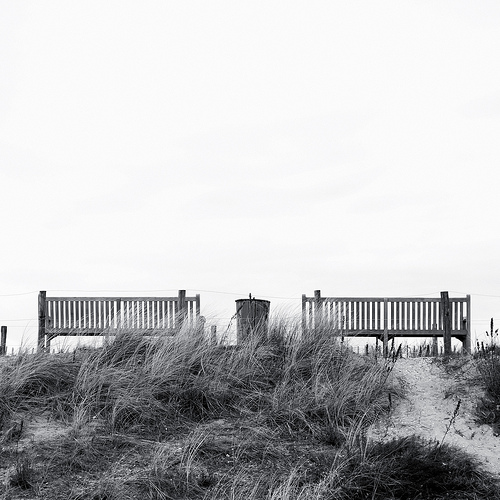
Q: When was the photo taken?
A: Daytime.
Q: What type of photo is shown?
A: Black and white.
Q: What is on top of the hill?
A: Benches.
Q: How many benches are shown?
A: Two.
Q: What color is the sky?
A: White.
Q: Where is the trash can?
A: Between the benches.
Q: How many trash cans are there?
A: One.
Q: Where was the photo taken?
A: Near benches.